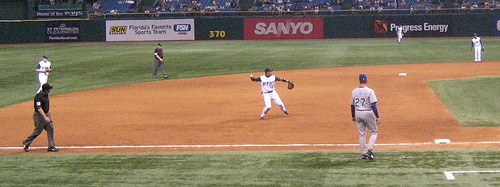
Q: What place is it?
A: It is a field.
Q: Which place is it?
A: It is a field.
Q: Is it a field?
A: Yes, it is a field.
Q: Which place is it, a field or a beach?
A: It is a field.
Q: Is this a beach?
A: No, it is a field.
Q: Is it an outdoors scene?
A: Yes, it is outdoors.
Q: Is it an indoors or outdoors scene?
A: It is outdoors.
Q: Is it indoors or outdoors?
A: It is outdoors.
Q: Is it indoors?
A: No, it is outdoors.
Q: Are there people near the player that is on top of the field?
A: Yes, there is a person near the player.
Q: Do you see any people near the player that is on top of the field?
A: Yes, there is a person near the player.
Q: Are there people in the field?
A: Yes, there is a person in the field.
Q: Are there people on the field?
A: Yes, there is a person on the field.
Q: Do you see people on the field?
A: Yes, there is a person on the field.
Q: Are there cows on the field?
A: No, there is a person on the field.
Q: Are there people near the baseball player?
A: Yes, there is a person near the player.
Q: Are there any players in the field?
A: Yes, there is a player in the field.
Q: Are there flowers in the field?
A: No, there is a player in the field.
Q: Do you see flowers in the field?
A: No, there is a player in the field.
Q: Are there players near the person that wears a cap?
A: Yes, there is a player near the person.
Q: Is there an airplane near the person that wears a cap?
A: No, there is a player near the person.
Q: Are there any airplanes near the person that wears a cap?
A: No, there is a player near the person.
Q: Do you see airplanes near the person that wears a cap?
A: No, there is a player near the person.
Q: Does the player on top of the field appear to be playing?
A: Yes, the player is playing.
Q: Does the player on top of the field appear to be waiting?
A: No, the player is playing.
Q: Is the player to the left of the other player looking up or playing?
A: The player is playing.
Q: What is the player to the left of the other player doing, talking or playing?
A: The player is playing.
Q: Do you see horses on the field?
A: No, there is a player on the field.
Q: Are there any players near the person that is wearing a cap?
A: Yes, there is a player near the person.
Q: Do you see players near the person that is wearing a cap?
A: Yes, there is a player near the person.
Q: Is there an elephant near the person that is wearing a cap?
A: No, there is a player near the person.